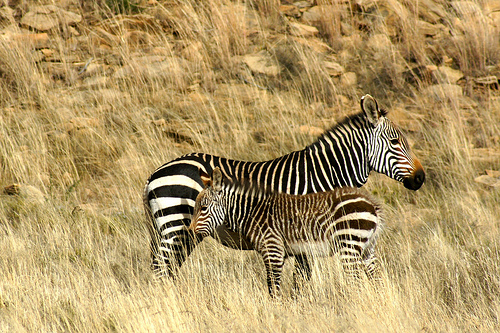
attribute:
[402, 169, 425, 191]
mouth — black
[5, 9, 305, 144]
tall grass — beige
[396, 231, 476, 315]
grass — tall, brown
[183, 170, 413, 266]
zebra —   zebra's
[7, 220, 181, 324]
grass — white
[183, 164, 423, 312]
zebra — partially brown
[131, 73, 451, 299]
zebra — adult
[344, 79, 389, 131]
ear — oval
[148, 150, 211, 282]
stripes — black, white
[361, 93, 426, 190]
zebra head —  black and white,  zebra's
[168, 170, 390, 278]
zebra —  baby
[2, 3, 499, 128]
rocks — tan, gray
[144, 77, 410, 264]
zebras —  two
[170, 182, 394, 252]
animal — black, white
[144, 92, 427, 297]
zebra —  mother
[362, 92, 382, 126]
ear —  big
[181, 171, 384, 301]
zebra — young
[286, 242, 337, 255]
patch — white